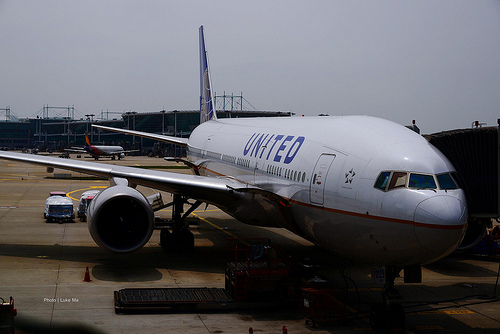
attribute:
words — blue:
[243, 125, 305, 169]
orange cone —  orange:
[74, 258, 95, 288]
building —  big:
[1, 103, 493, 228]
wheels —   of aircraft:
[159, 218, 199, 263]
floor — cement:
[5, 223, 85, 318]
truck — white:
[76, 187, 98, 221]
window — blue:
[372, 170, 392, 192]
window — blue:
[387, 169, 409, 189]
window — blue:
[408, 171, 439, 189]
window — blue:
[434, 172, 459, 189]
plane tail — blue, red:
[181, 19, 234, 134]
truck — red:
[181, 224, 314, 299]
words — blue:
[224, 119, 327, 174]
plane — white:
[1, 22, 498, 332]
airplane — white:
[57, 124, 144, 164]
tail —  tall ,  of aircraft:
[196, 21, 218, 128]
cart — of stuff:
[39, 185, 78, 222]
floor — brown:
[12, 221, 90, 309]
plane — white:
[72, 137, 125, 159]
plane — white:
[38, 76, 483, 301]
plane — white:
[5, 24, 495, 283]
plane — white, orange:
[65, 127, 131, 162]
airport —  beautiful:
[2, 0, 499, 333]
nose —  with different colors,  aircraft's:
[412, 193, 470, 254]